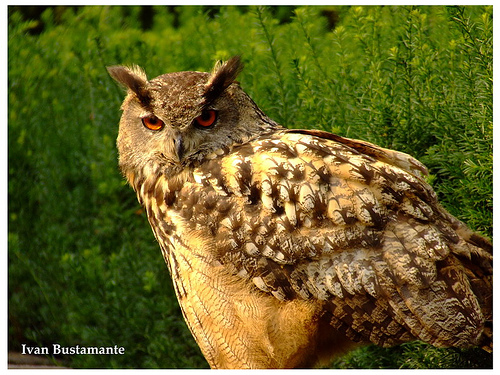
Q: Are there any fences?
A: No, there are no fences.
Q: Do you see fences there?
A: No, there are no fences.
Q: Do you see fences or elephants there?
A: No, there are no fences or elephants.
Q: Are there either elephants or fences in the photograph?
A: No, there are no fences or elephants.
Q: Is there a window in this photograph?
A: Yes, there is a window.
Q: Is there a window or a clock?
A: Yes, there is a window.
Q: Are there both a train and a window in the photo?
A: No, there is a window but no trains.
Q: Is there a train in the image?
A: No, there are no trains.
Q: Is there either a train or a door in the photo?
A: No, there are no trains or doors.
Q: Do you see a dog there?
A: No, there are no dogs.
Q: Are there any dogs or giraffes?
A: No, there are no dogs or giraffes.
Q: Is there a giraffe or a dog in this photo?
A: No, there are no dogs or giraffes.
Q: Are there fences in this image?
A: No, there are no fences.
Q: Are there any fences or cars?
A: No, there are no fences or cars.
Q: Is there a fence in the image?
A: No, there are no fences.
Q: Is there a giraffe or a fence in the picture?
A: No, there are no fences or giraffes.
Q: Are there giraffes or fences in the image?
A: No, there are no fences or giraffes.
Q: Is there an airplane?
A: No, there are no airplanes.